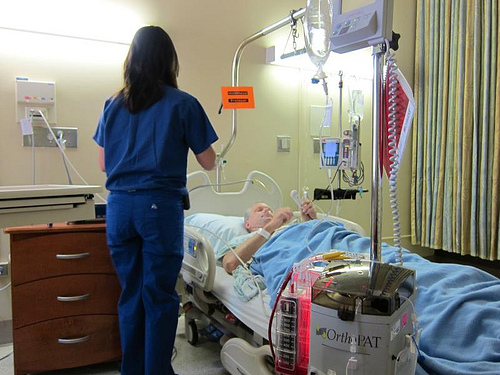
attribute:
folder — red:
[379, 60, 416, 181]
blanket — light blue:
[240, 218, 499, 373]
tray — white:
[0, 184, 105, 212]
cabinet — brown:
[1, 219, 116, 373]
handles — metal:
[52, 247, 94, 349]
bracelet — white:
[252, 225, 277, 243]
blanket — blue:
[259, 216, 496, 370]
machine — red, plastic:
[268, 261, 317, 373]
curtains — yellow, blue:
[407, 0, 499, 262]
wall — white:
[8, 1, 418, 247]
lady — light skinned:
[94, 26, 219, 373]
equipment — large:
[268, 248, 422, 373]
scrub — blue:
[96, 82, 216, 366]